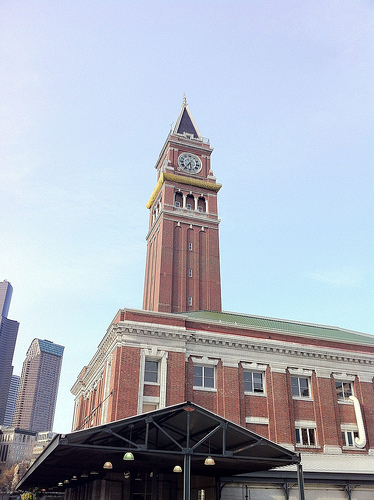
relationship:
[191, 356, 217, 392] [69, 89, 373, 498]
window of building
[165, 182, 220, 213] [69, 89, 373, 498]
windows are in building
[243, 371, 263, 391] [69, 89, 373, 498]
window are in building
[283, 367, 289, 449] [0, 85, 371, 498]
windows are in building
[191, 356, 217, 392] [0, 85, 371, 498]
window are in building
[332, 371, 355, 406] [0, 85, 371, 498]
window are in building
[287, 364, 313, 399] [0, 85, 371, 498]
window are in building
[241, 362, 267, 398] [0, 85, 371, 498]
window are in building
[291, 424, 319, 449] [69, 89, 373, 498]
window are in building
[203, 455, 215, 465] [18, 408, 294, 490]
lamp hanging on ceiling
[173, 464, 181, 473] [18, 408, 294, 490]
lamp hanging on ceiling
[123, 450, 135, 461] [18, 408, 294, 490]
lamp hanging on ceiling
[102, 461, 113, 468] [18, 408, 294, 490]
lamp hanging on ceiling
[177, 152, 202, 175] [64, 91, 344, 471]
clock on building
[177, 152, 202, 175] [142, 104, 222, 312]
clock on tower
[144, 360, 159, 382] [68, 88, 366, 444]
window in brick building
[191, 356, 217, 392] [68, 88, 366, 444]
window in brick building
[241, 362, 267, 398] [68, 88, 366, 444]
window in brick building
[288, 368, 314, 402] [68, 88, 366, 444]
window in brick building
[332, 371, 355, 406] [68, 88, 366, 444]
window in brick building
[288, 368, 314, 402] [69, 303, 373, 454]
window in brick building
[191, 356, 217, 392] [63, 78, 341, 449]
window in building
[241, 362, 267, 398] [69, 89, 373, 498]
window in building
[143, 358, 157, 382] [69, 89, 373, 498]
window in building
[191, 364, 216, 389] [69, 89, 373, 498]
window in building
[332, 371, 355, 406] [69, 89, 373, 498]
window in building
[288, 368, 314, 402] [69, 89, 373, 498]
window in building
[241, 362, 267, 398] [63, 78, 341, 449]
window in building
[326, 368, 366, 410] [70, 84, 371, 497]
window in brick building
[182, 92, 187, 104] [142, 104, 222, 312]
weather vane on tower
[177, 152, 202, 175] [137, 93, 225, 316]
clock on tower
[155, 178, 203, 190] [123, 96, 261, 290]
divider on tower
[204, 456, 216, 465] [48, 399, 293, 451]
lamp on ceiling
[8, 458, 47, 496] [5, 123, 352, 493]
trees in front of buildings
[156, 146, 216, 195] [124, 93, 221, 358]
clock on building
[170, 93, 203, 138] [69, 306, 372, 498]
steeple on building